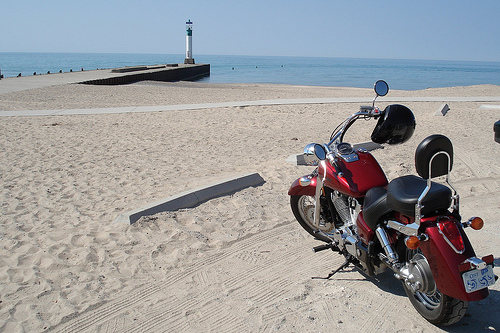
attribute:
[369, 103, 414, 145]
helmet — black, motorcycle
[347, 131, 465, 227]
seat — passenger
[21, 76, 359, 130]
sidewalk — cement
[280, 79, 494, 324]
motorcycle — red, black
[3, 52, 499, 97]
ocean — blue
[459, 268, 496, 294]
plate — license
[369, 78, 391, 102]
mirror — silver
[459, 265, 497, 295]
plate — white, license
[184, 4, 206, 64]
lighthouse — small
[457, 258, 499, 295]
license plate — white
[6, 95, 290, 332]
beach — empty, sandy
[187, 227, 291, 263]
beach — sandy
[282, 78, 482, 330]
motorbike — parked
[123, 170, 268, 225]
curb market — parking